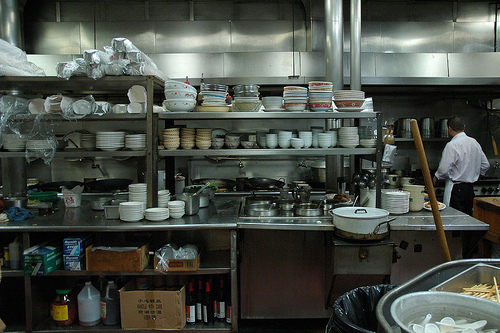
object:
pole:
[323, 0, 345, 90]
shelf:
[0, 196, 242, 332]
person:
[431, 114, 492, 216]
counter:
[0, 196, 242, 232]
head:
[446, 114, 467, 138]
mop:
[409, 118, 453, 262]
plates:
[381, 190, 411, 195]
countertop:
[236, 195, 491, 231]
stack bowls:
[334, 90, 365, 100]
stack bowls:
[284, 102, 307, 112]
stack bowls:
[232, 83, 261, 95]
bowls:
[339, 144, 360, 149]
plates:
[124, 133, 147, 135]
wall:
[17, 0, 500, 56]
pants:
[448, 181, 476, 218]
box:
[62, 237, 87, 272]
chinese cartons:
[43, 94, 80, 115]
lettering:
[135, 298, 163, 321]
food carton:
[59, 185, 86, 208]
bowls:
[331, 99, 366, 109]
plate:
[333, 108, 366, 113]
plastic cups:
[119, 219, 141, 223]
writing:
[136, 298, 164, 321]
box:
[117, 281, 188, 331]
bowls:
[284, 97, 308, 101]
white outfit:
[434, 131, 491, 183]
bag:
[322, 282, 407, 333]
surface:
[0, 195, 244, 232]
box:
[153, 247, 204, 272]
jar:
[48, 286, 78, 327]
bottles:
[77, 281, 103, 327]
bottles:
[99, 280, 121, 327]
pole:
[409, 118, 452, 262]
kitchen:
[0, 0, 498, 333]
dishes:
[197, 106, 232, 112]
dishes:
[164, 145, 180, 150]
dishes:
[95, 146, 124, 151]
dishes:
[119, 218, 144, 223]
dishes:
[389, 211, 408, 214]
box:
[85, 242, 151, 272]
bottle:
[186, 282, 197, 326]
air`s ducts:
[0, 0, 499, 77]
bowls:
[162, 99, 197, 113]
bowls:
[309, 101, 331, 112]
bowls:
[283, 85, 308, 91]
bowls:
[231, 100, 263, 112]